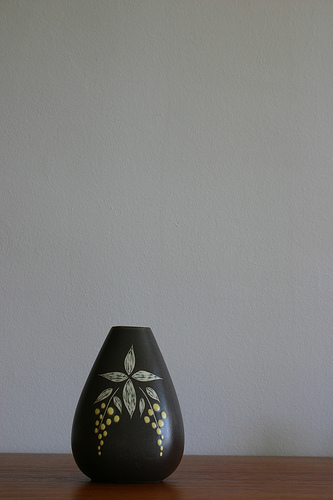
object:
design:
[97, 349, 169, 459]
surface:
[3, 450, 331, 498]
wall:
[0, 0, 331, 455]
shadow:
[68, 483, 181, 498]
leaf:
[120, 375, 136, 416]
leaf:
[137, 395, 144, 414]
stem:
[136, 384, 158, 422]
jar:
[69, 322, 185, 481]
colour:
[146, 397, 168, 450]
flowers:
[102, 342, 163, 423]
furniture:
[5, 451, 333, 500]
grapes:
[87, 390, 123, 458]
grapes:
[138, 399, 177, 455]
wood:
[189, 457, 289, 498]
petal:
[132, 369, 164, 384]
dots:
[142, 414, 151, 424]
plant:
[91, 340, 169, 460]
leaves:
[91, 388, 114, 404]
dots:
[114, 414, 120, 428]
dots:
[159, 450, 165, 456]